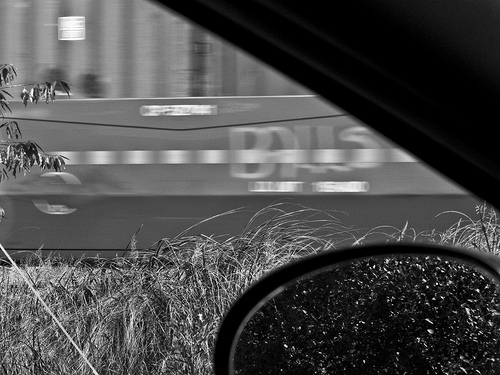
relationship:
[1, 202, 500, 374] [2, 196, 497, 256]
vegetation by road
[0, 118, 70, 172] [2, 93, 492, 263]
branches in front of train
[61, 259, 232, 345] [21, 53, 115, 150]
leaves on branches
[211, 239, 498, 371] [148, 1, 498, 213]
mirror on car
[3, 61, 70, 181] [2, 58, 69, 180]
leaves on branches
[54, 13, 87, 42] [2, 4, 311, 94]
sign on building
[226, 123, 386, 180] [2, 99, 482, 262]
writing on building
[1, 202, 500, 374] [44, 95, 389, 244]
vegetation by road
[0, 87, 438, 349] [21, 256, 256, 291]
train on tracks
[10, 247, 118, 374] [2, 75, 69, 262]
rope by tree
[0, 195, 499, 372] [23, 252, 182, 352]
grass in grass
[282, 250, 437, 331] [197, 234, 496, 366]
debris in object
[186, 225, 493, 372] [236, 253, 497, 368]
outline of mirror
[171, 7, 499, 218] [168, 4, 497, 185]
roof of car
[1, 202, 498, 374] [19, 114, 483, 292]
vegetation by road